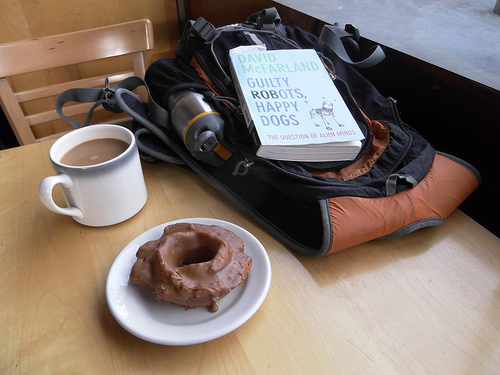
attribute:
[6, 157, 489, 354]
table — wooden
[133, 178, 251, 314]
cake — chocolate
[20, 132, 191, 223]
cup — white, here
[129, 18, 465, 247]
bag — black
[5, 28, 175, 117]
chair — wooden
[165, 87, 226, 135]
plastic — white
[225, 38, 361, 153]
book — titled, paperback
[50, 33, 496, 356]
backpack — here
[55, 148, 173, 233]
mug — grey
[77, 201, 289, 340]
plate — white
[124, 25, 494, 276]
backpack — orange, black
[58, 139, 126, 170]
drink — hot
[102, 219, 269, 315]
donut — glazd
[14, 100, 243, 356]
meal — here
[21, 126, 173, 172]
coffee — here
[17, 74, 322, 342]
breakfast — here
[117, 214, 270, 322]
doughnut — holed, brown, here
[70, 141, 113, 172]
sauce — here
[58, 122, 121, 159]
tea — brown